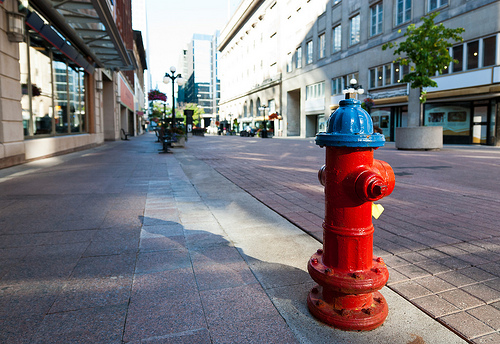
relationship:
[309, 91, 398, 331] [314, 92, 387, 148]
hydrant has a top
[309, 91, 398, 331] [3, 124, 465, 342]
hydrant on sidewalk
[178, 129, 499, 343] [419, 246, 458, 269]
floor made of bricks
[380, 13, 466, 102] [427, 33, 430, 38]
tree has leaves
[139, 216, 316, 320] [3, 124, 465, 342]
shadow on ground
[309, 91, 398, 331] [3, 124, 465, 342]
fire hydrant on sidewalk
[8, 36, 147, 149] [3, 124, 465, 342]
stores by walkway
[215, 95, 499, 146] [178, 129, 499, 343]
stores by walkway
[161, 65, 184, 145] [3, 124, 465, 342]
streetlight by walkway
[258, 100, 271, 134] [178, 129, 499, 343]
streetlight by walkway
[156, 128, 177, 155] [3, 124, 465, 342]
bench on walkway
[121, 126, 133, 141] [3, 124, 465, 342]
bench on walkway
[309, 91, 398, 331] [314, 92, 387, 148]
fire hydrant has a top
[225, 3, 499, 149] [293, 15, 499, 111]
building has windows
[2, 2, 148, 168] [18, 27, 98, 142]
building has windows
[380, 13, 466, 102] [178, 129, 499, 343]
tree by walkway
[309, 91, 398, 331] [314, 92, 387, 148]
fire hydrant has a blue top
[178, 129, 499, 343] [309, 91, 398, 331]
street next to fire hydrant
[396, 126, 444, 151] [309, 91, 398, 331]
planter behind fire hydrant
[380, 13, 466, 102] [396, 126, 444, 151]
tree in planter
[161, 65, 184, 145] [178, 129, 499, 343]
street light near street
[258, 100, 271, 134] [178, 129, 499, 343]
street light near street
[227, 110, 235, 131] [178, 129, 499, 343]
street light near street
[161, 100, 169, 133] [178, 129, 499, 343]
street light near street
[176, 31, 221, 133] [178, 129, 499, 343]
building behind street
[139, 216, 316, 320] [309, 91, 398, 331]
shadow of fire hydrant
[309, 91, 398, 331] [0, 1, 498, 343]
fire hydrant in city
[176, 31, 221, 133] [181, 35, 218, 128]
building has windows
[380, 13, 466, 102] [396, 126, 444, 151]
tree in pot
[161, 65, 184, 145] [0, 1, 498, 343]
light fixture in downtown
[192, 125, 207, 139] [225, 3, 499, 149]
table outside building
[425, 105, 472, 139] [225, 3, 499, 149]
sign on building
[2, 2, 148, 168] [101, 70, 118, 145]
building has a doorway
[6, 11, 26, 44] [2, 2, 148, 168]
light fixture on building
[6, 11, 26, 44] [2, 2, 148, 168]
light fixture on side of building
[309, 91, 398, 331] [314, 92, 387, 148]
hydrant has a blue top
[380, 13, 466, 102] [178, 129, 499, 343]
tree across walkway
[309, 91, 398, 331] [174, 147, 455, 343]
hydrant on curb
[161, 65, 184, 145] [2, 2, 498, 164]
streetlight in background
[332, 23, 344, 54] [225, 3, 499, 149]
window on building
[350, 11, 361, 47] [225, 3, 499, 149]
window on building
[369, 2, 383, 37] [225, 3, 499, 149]
window on building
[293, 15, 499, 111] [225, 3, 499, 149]
bunch of windows on building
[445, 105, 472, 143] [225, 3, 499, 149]
advertisement on building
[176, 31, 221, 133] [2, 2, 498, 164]
building in background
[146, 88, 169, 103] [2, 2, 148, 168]
awning on building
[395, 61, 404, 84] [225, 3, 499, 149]
lights are inside building